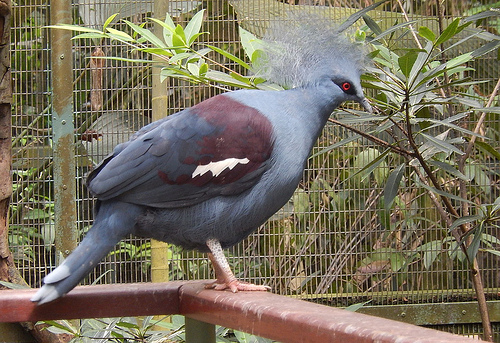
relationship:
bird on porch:
[30, 7, 371, 304] [16, 263, 445, 336]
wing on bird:
[81, 92, 265, 195] [30, 7, 371, 304]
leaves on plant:
[39, 5, 236, 87] [41, 0, 493, 340]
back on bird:
[204, 239, 239, 281] [30, 7, 371, 304]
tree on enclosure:
[42, 2, 499, 341] [1, 0, 498, 342]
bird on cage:
[30, 7, 371, 304] [0, 0, 498, 341]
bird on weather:
[30, 54, 371, 304] [252, 7, 374, 84]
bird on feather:
[30, 7, 371, 304] [192, 157, 250, 180]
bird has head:
[30, 7, 371, 304] [311, 60, 375, 116]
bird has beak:
[30, 7, 371, 304] [355, 92, 376, 119]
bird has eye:
[30, 7, 371, 304] [332, 73, 364, 102]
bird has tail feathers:
[30, 7, 371, 304] [31, 192, 144, 305]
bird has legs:
[30, 7, 371, 304] [202, 239, 274, 296]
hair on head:
[261, 20, 368, 85] [296, 56, 370, 115]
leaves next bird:
[39, 5, 236, 87] [30, 7, 371, 304]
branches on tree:
[252, 11, 471, 237] [369, 22, 497, 294]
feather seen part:
[192, 157, 250, 180] [216, 128, 251, 152]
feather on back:
[17, 209, 107, 308] [29, 158, 143, 308]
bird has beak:
[30, 7, 371, 304] [357, 94, 374, 113]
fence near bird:
[309, 153, 391, 295] [34, 60, 381, 323]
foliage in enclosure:
[3, 2, 498, 342] [22, 14, 495, 285]